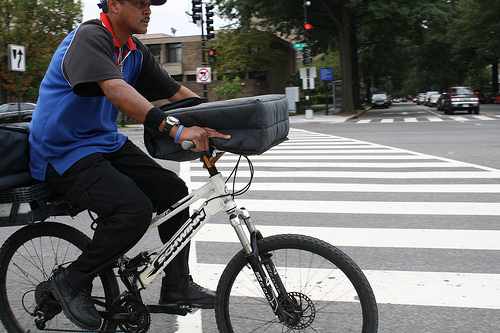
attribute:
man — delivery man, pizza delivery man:
[28, 0, 231, 332]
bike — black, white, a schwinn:
[1, 139, 377, 333]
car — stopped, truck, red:
[442, 84, 482, 116]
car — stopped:
[437, 92, 447, 110]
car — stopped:
[426, 93, 441, 108]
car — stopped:
[416, 93, 426, 105]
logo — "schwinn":
[147, 209, 207, 278]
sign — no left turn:
[197, 65, 214, 83]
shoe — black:
[47, 268, 103, 331]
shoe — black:
[158, 277, 216, 310]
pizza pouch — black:
[144, 94, 291, 163]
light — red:
[305, 24, 311, 30]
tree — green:
[208, 0, 462, 114]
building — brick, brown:
[132, 30, 296, 114]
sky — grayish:
[0, 1, 240, 37]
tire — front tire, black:
[215, 233, 379, 332]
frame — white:
[112, 174, 302, 333]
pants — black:
[45, 138, 190, 292]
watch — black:
[160, 116, 178, 138]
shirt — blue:
[27, 13, 182, 181]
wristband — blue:
[175, 125, 182, 144]